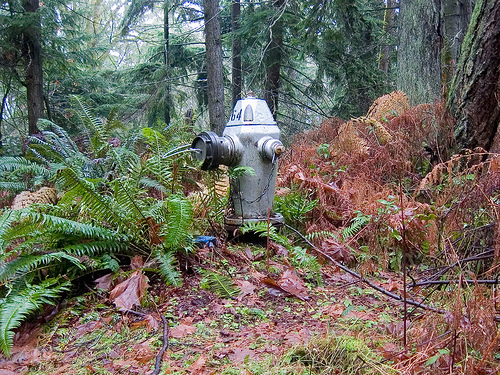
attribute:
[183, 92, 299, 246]
hydrant — silver, grey, metal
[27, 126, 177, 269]
shrubbery — green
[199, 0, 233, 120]
trunks — tall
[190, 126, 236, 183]
cylinder — larg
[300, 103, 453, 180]
bushes — dead